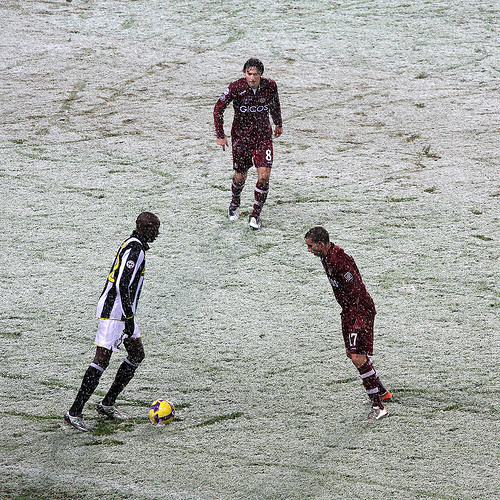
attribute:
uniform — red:
[316, 249, 388, 361]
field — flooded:
[89, 99, 474, 451]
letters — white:
[233, 101, 275, 116]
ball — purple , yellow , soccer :
[145, 389, 186, 423]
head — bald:
[101, 191, 192, 265]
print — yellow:
[92, 232, 139, 272]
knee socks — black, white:
[87, 350, 146, 377]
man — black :
[9, 159, 220, 431]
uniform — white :
[87, 230, 176, 336]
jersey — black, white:
[90, 231, 155, 328]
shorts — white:
[89, 302, 133, 374]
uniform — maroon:
[320, 241, 388, 410]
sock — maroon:
[363, 361, 390, 401]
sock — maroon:
[354, 358, 385, 406]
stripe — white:
[357, 364, 375, 380]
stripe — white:
[366, 384, 379, 397]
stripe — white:
[377, 388, 388, 399]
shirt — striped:
[91, 233, 147, 324]